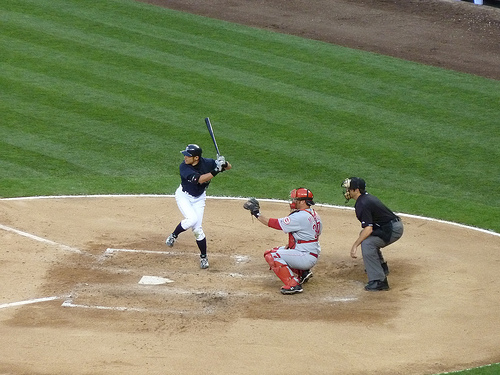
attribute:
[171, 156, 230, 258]
uniform — blue , white 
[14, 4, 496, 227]
grass — green 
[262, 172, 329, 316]
catchers mask — red 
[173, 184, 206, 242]
pants — white 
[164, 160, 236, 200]
shirt — black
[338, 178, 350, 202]
mask — black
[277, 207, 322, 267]
gray uniform — grey 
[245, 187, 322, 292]
catcher — catcher's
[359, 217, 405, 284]
pants — gray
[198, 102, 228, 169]
bat — black 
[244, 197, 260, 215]
mitt — black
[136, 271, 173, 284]
plate — white, home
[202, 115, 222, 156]
bat — black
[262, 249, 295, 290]
shin guard — red